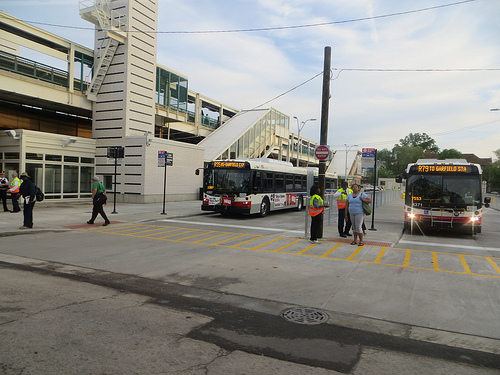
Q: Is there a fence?
A: No, there are no fences.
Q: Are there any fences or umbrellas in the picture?
A: No, there are no fences or umbrellas.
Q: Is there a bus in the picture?
A: Yes, there are buses.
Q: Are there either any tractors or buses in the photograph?
A: Yes, there are buses.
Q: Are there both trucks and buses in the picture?
A: No, there are buses but no trucks.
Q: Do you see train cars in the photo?
A: No, there are no train cars.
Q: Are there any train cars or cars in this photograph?
A: No, there are no train cars or cars.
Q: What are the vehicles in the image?
A: The vehicles are buses.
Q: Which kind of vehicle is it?
A: The vehicles are buses.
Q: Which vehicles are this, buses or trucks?
A: These are buses.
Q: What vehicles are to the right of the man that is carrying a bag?
A: The vehicles are buses.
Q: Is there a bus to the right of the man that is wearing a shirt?
A: Yes, there are buses to the right of the man.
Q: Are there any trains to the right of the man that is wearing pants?
A: No, there are buses to the right of the man.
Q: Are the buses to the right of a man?
A: Yes, the buses are to the right of a man.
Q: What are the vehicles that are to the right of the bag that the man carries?
A: The vehicles are buses.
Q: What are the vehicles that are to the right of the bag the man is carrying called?
A: The vehicles are buses.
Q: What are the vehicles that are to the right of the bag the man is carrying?
A: The vehicles are buses.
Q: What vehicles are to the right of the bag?
A: The vehicles are buses.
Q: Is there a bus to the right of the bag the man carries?
A: Yes, there are buses to the right of the bag.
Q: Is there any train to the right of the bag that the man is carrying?
A: No, there are buses to the right of the bag.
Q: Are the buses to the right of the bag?
A: Yes, the buses are to the right of the bag.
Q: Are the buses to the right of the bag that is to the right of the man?
A: Yes, the buses are to the right of the bag.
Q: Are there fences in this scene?
A: No, there are no fences.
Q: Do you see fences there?
A: No, there are no fences.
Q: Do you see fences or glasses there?
A: No, there are no fences or glasses.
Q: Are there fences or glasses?
A: No, there are no fences or glasses.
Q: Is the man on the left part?
A: Yes, the man is on the left of the image.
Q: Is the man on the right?
A: No, the man is on the left of the image.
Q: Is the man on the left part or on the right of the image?
A: The man is on the left of the image.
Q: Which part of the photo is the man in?
A: The man is on the left of the image.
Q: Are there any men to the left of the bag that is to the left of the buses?
A: Yes, there is a man to the left of the bag.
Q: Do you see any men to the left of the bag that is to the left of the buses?
A: Yes, there is a man to the left of the bag.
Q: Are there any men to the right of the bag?
A: No, the man is to the left of the bag.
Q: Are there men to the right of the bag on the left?
A: No, the man is to the left of the bag.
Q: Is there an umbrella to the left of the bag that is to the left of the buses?
A: No, there is a man to the left of the bag.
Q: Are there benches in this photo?
A: No, there are no benches.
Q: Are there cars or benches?
A: No, there are no benches or cars.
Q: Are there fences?
A: No, there are no fences.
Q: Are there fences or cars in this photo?
A: No, there are no fences or cars.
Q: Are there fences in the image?
A: No, there are no fences.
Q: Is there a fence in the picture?
A: No, there are no fences.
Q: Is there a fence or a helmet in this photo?
A: No, there are no fences or helmets.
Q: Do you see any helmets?
A: No, there are no helmets.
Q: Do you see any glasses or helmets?
A: No, there are no helmets or glasses.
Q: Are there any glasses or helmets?
A: No, there are no helmets or glasses.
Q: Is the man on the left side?
A: Yes, the man is on the left of the image.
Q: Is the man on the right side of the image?
A: No, the man is on the left of the image.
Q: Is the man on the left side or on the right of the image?
A: The man is on the left of the image.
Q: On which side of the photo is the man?
A: The man is on the left of the image.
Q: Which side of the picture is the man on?
A: The man is on the left of the image.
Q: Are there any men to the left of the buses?
A: Yes, there is a man to the left of the buses.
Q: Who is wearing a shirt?
A: The man is wearing a shirt.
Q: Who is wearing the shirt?
A: The man is wearing a shirt.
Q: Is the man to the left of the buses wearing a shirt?
A: Yes, the man is wearing a shirt.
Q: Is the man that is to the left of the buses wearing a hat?
A: No, the man is wearing a shirt.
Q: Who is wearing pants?
A: The man is wearing pants.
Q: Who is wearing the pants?
A: The man is wearing pants.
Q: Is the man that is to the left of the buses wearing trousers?
A: Yes, the man is wearing trousers.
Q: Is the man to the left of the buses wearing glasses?
A: No, the man is wearing trousers.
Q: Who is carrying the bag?
A: The man is carrying the bag.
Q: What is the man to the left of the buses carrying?
A: The man is carrying a bag.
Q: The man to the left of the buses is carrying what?
A: The man is carrying a bag.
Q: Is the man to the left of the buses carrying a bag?
A: Yes, the man is carrying a bag.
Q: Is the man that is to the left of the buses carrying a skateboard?
A: No, the man is carrying a bag.